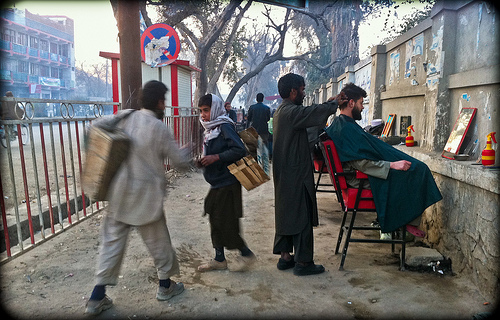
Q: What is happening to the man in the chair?
A: Getting his hair cut.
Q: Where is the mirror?
A: In front of the man.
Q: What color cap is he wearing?
A: Blue.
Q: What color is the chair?
A: Red.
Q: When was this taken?
A: Spring.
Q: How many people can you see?
A: Five.